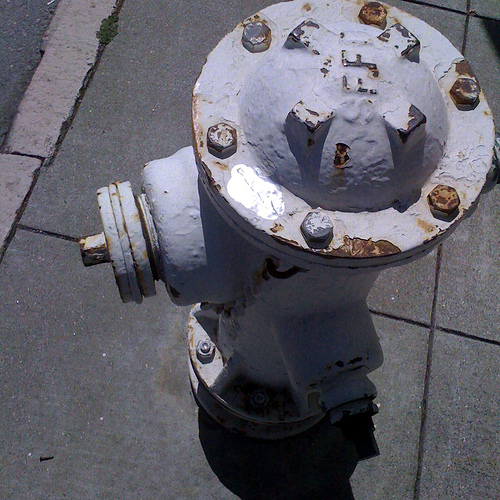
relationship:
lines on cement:
[370, 241, 499, 498] [2, 2, 499, 498]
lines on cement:
[17, 223, 80, 246] [2, 2, 499, 498]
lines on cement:
[408, 0, 499, 55] [2, 2, 499, 498]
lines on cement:
[1, 150, 50, 161] [2, 2, 499, 498]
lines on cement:
[0, 223, 17, 262] [2, 2, 499, 498]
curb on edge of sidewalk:
[0, 0, 110, 190] [3, 4, 498, 498]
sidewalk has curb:
[3, 4, 498, 498] [0, 3, 120, 259]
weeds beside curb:
[100, 7, 122, 41] [0, 3, 120, 259]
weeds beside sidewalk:
[100, 7, 122, 41] [3, 4, 498, 498]